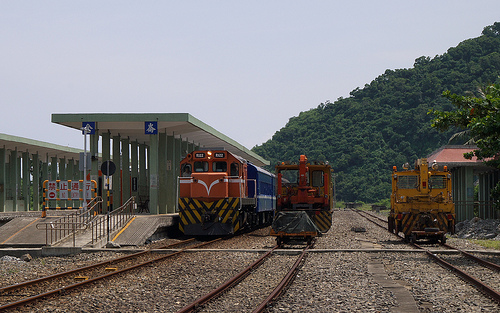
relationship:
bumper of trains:
[179, 198, 233, 233] [193, 102, 478, 266]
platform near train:
[47, 104, 202, 221] [175, 141, 281, 246]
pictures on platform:
[144, 121, 158, 135] [1, 113, 271, 243]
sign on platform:
[80, 121, 96, 135] [1, 113, 271, 243]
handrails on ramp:
[34, 189, 138, 251] [0, 210, 164, 241]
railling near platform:
[32, 195, 136, 229] [44, 186, 185, 242]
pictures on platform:
[144, 121, 158, 135] [1, 190, 182, 250]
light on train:
[204, 150, 214, 159] [167, 147, 270, 219]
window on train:
[187, 157, 216, 169] [167, 145, 267, 244]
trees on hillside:
[249, 22, 499, 201] [235, 20, 485, 179]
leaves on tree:
[465, 92, 497, 155] [425, 83, 498, 230]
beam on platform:
[146, 134, 160, 212] [6, 202, 181, 248]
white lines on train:
[169, 180, 269, 201] [175, 147, 288, 237]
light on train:
[206, 147, 214, 159] [175, 141, 281, 246]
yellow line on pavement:
[110, 212, 137, 244] [10, 206, 185, 254]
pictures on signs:
[82, 121, 160, 131] [78, 119, 158, 134]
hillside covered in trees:
[354, 62, 477, 177] [353, 35, 498, 172]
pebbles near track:
[274, 191, 476, 311] [192, 240, 317, 312]